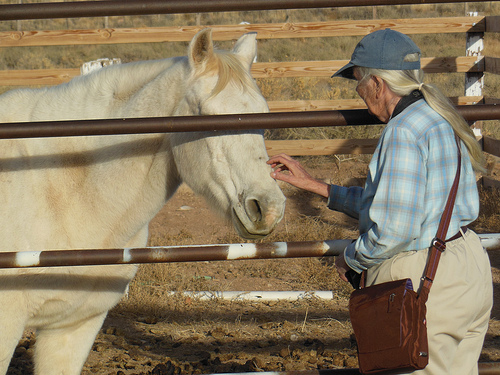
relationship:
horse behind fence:
[0, 26, 286, 374] [0, 0, 499, 267]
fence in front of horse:
[0, 0, 499, 267] [0, 26, 286, 374]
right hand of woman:
[268, 154, 330, 198] [264, 28, 495, 374]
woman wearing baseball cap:
[264, 28, 495, 374] [330, 26, 419, 79]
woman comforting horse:
[264, 28, 495, 374] [0, 26, 286, 374]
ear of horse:
[188, 24, 215, 68] [0, 26, 286, 374]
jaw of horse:
[230, 205, 281, 239] [0, 26, 286, 374]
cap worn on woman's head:
[330, 26, 419, 79] [349, 29, 422, 121]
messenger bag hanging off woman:
[348, 130, 464, 375] [264, 28, 495, 374]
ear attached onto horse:
[188, 24, 215, 68] [0, 26, 286, 374]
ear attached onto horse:
[232, 31, 260, 68] [0, 26, 286, 374]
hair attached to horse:
[193, 43, 257, 100] [0, 26, 286, 374]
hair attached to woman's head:
[359, 49, 491, 174] [349, 29, 422, 121]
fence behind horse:
[1, 11, 499, 189] [0, 26, 286, 374]